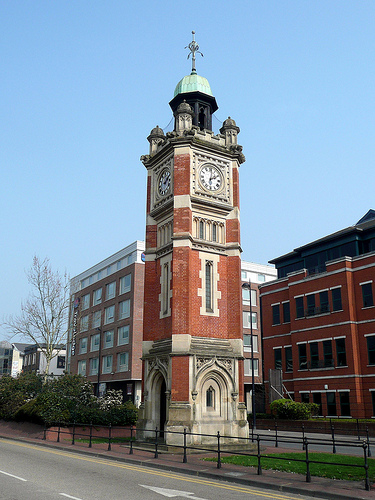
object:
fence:
[40, 419, 371, 494]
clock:
[189, 149, 234, 203]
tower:
[132, 30, 251, 448]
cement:
[188, 143, 235, 216]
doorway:
[145, 355, 169, 443]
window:
[204, 384, 220, 412]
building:
[62, 239, 276, 417]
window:
[119, 298, 132, 320]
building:
[259, 251, 374, 420]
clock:
[148, 155, 174, 207]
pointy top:
[169, 30, 218, 99]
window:
[202, 258, 215, 318]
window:
[155, 262, 172, 320]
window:
[210, 218, 220, 243]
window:
[198, 218, 208, 241]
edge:
[1, 437, 337, 499]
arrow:
[136, 483, 211, 499]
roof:
[167, 76, 215, 101]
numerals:
[208, 184, 213, 192]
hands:
[163, 174, 173, 189]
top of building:
[67, 238, 276, 294]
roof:
[266, 208, 374, 268]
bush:
[268, 398, 319, 420]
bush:
[88, 394, 141, 428]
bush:
[30, 372, 100, 427]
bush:
[2, 370, 45, 419]